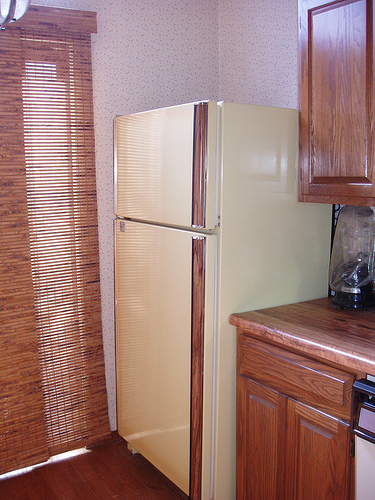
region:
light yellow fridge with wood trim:
[102, 97, 328, 498]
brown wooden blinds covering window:
[5, 2, 111, 459]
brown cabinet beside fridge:
[238, 288, 369, 495]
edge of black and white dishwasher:
[350, 374, 368, 493]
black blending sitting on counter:
[325, 205, 370, 311]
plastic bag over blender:
[321, 205, 371, 287]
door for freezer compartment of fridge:
[114, 101, 215, 227]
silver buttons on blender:
[333, 282, 362, 295]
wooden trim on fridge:
[190, 101, 209, 497]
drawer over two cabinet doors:
[236, 335, 354, 415]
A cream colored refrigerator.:
[110, 101, 335, 499]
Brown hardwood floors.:
[1, 437, 188, 498]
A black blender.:
[332, 206, 373, 309]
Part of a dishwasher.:
[348, 379, 373, 498]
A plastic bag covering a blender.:
[329, 206, 374, 290]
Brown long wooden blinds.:
[2, 4, 113, 481]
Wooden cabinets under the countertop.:
[234, 334, 359, 499]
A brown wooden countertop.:
[229, 293, 374, 382]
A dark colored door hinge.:
[349, 440, 354, 457]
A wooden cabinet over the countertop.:
[297, 4, 374, 205]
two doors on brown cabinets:
[235, 374, 346, 498]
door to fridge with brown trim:
[109, 219, 211, 499]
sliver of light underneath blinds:
[3, 450, 96, 476]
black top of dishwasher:
[346, 376, 374, 436]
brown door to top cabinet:
[295, 3, 371, 201]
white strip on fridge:
[207, 101, 220, 497]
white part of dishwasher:
[353, 437, 374, 498]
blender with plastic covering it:
[324, 208, 371, 308]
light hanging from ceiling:
[2, 0, 29, 27]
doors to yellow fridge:
[110, 107, 219, 493]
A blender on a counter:
[315, 208, 373, 321]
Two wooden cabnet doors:
[235, 325, 345, 450]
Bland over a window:
[13, 9, 107, 252]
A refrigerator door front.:
[117, 217, 217, 491]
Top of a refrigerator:
[112, 99, 296, 228]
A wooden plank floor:
[10, 455, 145, 493]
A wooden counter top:
[279, 308, 362, 344]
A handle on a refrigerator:
[191, 106, 207, 232]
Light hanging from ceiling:
[2, 0, 27, 34]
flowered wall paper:
[103, 43, 227, 96]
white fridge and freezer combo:
[109, 106, 338, 499]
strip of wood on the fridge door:
[185, 233, 209, 499]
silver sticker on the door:
[116, 220, 128, 232]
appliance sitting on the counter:
[327, 205, 372, 318]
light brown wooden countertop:
[222, 293, 374, 381]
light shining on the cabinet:
[298, 0, 360, 41]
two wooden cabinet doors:
[239, 380, 345, 498]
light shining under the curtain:
[1, 433, 85, 484]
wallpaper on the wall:
[218, 5, 301, 110]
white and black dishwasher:
[349, 375, 373, 498]